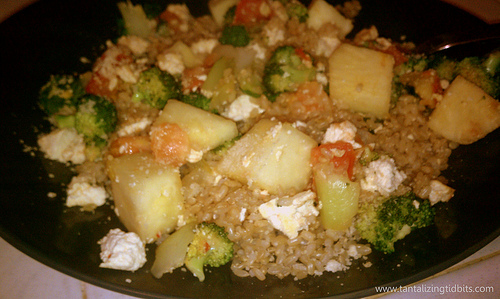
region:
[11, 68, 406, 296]
the plate is black and round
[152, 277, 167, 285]
part of a plate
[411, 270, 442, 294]
part of a graphic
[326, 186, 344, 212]
edge of a potato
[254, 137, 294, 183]
part of a potato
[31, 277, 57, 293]
part of a cloth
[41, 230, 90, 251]
part of a plate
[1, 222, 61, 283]
edge of a plate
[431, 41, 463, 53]
edge of a spoon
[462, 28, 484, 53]
part of a spoon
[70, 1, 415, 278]
A rice dish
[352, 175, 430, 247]
broccoli on the rice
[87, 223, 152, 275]
Crumbled cheese on the plate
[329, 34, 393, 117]
Chunk in the food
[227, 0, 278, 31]
Tomato in the dinner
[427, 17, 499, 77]
the utensile on the palte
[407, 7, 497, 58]
The silverware in the corner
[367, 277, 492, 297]
URL in the corner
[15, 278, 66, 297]
The white counter top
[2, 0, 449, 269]
Dinner on the black plate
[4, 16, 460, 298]
the plate is black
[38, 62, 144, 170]
broccoli is on plate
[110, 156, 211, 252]
pineapples are on plate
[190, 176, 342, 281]
rice is on plate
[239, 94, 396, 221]
chicken is on plate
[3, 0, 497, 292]
the plate is round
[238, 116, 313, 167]
chicken pieces on pineapple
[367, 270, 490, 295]
website listed on bottom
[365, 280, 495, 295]
the website is www.tantalizingtidbits.com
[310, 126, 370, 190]
red food on pineapple